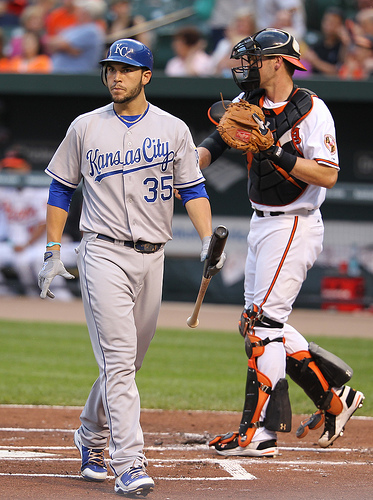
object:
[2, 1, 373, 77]
crowd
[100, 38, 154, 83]
helmet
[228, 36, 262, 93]
mask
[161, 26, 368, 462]
catcher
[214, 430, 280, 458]
shoe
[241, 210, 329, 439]
pants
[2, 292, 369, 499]
baseball field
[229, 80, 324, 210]
chest protector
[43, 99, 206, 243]
jersey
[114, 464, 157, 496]
cleats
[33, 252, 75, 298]
glove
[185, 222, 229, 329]
bat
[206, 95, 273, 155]
mitt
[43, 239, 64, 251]
wristband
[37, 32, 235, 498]
batter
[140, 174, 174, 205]
"35"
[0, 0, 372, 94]
bleachers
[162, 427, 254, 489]
markings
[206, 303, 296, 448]
guards